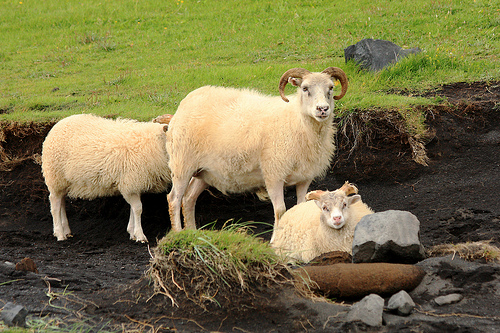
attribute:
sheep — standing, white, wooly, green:
[27, 105, 166, 250]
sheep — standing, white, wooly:
[174, 59, 351, 188]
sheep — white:
[293, 182, 363, 251]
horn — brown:
[270, 68, 302, 102]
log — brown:
[320, 258, 424, 292]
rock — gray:
[347, 36, 386, 66]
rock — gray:
[368, 211, 422, 255]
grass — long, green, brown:
[179, 225, 242, 253]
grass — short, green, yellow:
[54, 32, 97, 61]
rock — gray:
[6, 298, 31, 327]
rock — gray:
[353, 291, 379, 327]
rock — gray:
[396, 289, 411, 311]